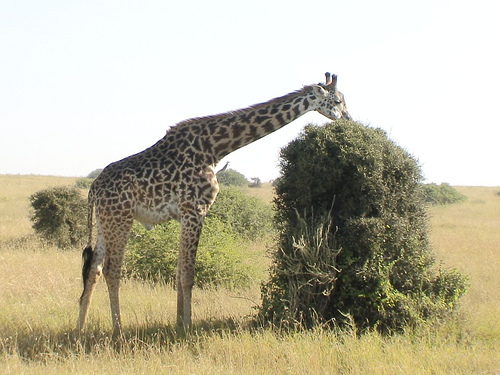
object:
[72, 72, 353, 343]
giraffe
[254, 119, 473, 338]
tree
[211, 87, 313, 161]
neck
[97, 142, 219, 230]
body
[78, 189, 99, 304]
tail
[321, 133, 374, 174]
food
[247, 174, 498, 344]
field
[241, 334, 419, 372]
grass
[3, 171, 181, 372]
field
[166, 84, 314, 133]
brown mane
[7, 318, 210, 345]
shadow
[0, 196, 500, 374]
grassland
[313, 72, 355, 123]
head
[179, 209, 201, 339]
brown legs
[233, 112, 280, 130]
spotted neck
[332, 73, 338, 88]
horned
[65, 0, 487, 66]
sky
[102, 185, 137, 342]
hind legs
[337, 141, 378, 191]
green